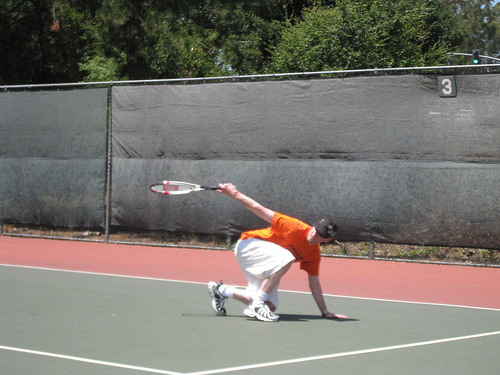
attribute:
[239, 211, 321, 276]
shirt — orange 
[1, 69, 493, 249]
fencing — black 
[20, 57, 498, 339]
tennis court — green 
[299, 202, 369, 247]
hat — black 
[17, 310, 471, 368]
lines — white 